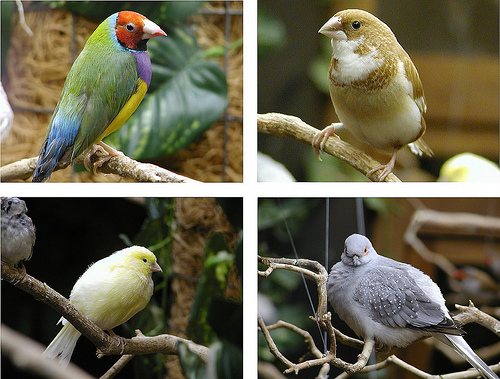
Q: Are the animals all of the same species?
A: Yes, all the animals are birds.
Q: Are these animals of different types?
A: No, all the animals are birds.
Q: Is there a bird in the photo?
A: Yes, there is a bird.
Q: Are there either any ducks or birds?
A: Yes, there is a bird.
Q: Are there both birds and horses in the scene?
A: No, there is a bird but no horses.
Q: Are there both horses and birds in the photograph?
A: No, there is a bird but no horses.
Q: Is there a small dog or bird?
A: Yes, there is a small bird.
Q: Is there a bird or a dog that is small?
A: Yes, the bird is small.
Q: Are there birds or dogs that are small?
A: Yes, the bird is small.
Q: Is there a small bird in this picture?
A: Yes, there is a small bird.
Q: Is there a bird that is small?
A: Yes, there is a bird that is small.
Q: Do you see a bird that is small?
A: Yes, there is a bird that is small.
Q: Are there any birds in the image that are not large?
A: Yes, there is a small bird.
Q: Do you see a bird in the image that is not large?
A: Yes, there is a small bird.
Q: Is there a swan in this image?
A: No, there are no swans.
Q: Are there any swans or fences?
A: No, there are no swans or fences.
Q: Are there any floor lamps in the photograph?
A: No, there are no floor lamps.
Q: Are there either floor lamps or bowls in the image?
A: No, there are no floor lamps or bowls.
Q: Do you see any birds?
A: Yes, there are birds.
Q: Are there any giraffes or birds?
A: Yes, there are birds.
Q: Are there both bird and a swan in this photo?
A: No, there are birds but no swans.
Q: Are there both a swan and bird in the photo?
A: No, there are birds but no swans.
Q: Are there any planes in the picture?
A: No, there are no planes.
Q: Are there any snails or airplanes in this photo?
A: No, there are no airplanes or snails.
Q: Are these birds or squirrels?
A: These are birds.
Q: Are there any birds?
A: Yes, there is a bird.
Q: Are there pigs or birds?
A: Yes, there is a bird.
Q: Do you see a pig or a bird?
A: Yes, there is a bird.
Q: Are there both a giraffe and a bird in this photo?
A: No, there is a bird but no giraffes.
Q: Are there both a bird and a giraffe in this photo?
A: No, there is a bird but no giraffes.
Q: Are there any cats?
A: No, there are no cats.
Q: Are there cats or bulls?
A: No, there are no cats or bulls.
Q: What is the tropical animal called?
A: The animal is a bird.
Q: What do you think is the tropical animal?
A: The animal is a bird.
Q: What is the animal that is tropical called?
A: The animal is a bird.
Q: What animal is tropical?
A: The animal is a bird.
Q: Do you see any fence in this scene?
A: No, there are no fences.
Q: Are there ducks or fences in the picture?
A: No, there are no fences or ducks.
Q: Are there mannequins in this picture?
A: No, there are no mannequins.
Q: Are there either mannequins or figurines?
A: No, there are no mannequins or figurines.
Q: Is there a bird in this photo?
A: Yes, there is a bird.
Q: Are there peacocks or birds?
A: Yes, there is a bird.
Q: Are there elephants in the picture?
A: No, there are no elephants.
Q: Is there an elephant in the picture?
A: No, there are no elephants.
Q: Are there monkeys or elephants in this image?
A: No, there are no elephants or monkeys.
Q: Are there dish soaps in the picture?
A: No, there are no dish soaps.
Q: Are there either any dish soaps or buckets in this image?
A: No, there are no dish soaps or buckets.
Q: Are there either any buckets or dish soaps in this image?
A: No, there are no dish soaps or buckets.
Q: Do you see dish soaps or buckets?
A: No, there are no dish soaps or buckets.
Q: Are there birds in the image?
A: Yes, there is a bird.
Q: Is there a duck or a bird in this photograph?
A: Yes, there is a bird.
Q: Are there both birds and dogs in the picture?
A: No, there is a bird but no dogs.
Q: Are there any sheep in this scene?
A: No, there are no sheep.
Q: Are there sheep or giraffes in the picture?
A: No, there are no sheep or giraffes.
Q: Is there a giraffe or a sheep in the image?
A: No, there are no sheep or giraffes.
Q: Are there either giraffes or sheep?
A: No, there are no sheep or giraffes.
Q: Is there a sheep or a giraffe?
A: No, there are no sheep or giraffes.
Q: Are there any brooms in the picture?
A: No, there are no brooms.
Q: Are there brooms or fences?
A: No, there are no brooms or fences.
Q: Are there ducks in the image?
A: No, there are no ducks.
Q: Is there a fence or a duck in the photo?
A: No, there are no ducks or fences.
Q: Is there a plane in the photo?
A: No, there are no airplanes.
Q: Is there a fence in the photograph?
A: No, there are no fences.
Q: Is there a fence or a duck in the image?
A: No, there are no fences or ducks.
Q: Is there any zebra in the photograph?
A: No, there are no zebras.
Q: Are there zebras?
A: No, there are no zebras.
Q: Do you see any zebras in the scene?
A: No, there are no zebras.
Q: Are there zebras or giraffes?
A: No, there are no zebras or giraffes.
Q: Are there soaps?
A: No, there are no soaps.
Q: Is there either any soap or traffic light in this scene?
A: No, there are no soaps or traffic lights.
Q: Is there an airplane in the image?
A: No, there are no airplanes.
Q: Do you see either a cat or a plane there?
A: No, there are no airplanes or cats.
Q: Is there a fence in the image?
A: No, there are no fences.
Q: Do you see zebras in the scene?
A: No, there are no zebras.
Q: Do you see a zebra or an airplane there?
A: No, there are no zebras or airplanes.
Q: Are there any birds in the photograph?
A: Yes, there are birds.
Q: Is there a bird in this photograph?
A: Yes, there are birds.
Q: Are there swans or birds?
A: Yes, there are birds.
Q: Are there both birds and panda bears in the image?
A: No, there are birds but no pandas.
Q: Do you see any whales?
A: No, there are no whales.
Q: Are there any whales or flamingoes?
A: No, there are no whales or flamingoes.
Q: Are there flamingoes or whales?
A: No, there are no whales or flamingoes.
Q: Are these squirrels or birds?
A: These are birds.